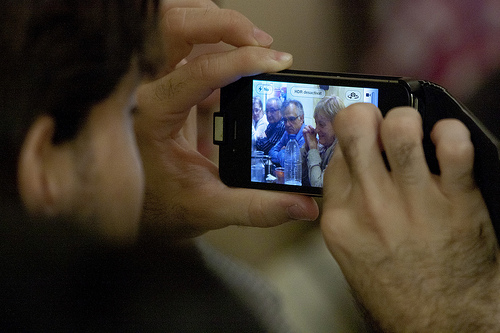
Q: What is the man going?
A: Taking picture.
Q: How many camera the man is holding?
A: One.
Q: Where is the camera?
A: Being held by the man.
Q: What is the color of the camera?
A: Black.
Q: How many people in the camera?
A: Four.